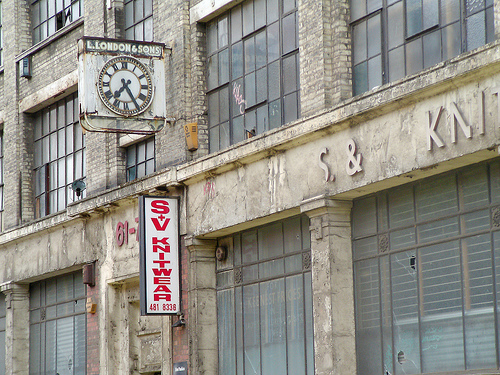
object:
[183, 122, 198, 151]
container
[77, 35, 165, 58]
rusty sign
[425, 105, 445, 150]
k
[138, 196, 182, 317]
sign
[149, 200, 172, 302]
lettering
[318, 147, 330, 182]
s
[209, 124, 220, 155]
windows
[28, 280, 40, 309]
windows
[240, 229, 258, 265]
windows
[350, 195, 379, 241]
windows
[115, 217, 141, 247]
sign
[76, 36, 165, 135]
clock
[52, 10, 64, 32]
broken window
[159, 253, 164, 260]
letters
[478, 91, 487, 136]
letters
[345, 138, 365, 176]
& sign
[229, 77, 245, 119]
window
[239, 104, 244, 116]
letters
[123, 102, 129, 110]
roman numerals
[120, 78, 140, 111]
hands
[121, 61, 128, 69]
roman numberals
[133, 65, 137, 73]
roman numberals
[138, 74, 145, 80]
roman numberals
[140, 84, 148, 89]
roman numberals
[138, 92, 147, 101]
roman numberals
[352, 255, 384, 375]
window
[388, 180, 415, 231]
window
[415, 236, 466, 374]
window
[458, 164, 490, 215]
window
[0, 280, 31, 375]
column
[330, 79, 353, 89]
bricks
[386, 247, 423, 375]
window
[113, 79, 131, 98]
hands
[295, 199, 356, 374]
column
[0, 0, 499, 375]
building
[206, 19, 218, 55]
window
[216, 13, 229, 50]
window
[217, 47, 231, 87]
window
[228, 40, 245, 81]
window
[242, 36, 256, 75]
window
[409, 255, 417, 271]
hole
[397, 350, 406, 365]
hole